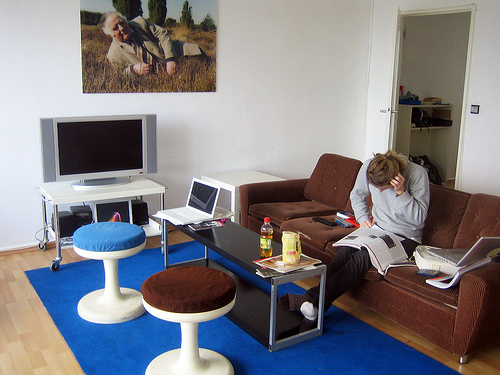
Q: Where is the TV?
A: By the wall.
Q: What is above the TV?
A: A picture.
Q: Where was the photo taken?
A: In a living room.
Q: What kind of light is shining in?
A: Sunlight.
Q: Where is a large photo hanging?
A: On the wall.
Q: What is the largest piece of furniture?
A: A couch.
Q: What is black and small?
A: The coffee table.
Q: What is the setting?
A: A living room.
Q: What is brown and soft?
A: The couch.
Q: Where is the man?
A: In the living room.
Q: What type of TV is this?
A: A flat screen.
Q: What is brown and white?
A: The stool.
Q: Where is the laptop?
A: On the table.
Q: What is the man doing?
A: Reading.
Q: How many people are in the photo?
A: One.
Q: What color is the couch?
A: Brown.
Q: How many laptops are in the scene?
A: One.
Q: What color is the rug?
A: Blue.